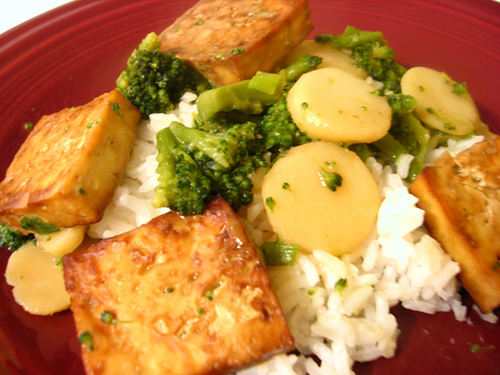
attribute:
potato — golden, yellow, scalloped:
[258, 138, 381, 261]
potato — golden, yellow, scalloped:
[284, 65, 393, 148]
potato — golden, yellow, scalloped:
[398, 61, 482, 141]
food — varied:
[0, 0, 499, 373]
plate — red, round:
[1, 1, 499, 372]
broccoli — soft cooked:
[117, 30, 321, 219]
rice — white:
[87, 90, 486, 373]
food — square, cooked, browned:
[64, 190, 295, 371]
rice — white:
[271, 158, 496, 373]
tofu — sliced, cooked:
[0, 88, 142, 228]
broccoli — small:
[320, 168, 344, 191]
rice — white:
[75, 56, 485, 367]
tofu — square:
[53, 172, 297, 371]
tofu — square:
[2, 81, 145, 233]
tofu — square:
[148, 3, 321, 95]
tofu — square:
[408, 109, 493, 318]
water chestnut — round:
[259, 138, 395, 268]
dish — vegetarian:
[7, 10, 494, 372]